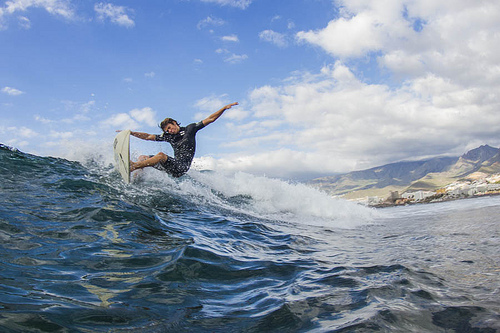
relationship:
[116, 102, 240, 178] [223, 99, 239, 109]
man has hand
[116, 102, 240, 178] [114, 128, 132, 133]
man has hand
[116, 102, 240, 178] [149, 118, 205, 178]
man wearing wet suit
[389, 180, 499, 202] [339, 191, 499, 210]
buildings on coast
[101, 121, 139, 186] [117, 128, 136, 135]
surfboard has tip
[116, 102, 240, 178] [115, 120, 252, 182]
man wearing navy blue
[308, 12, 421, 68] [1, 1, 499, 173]
clouds in sky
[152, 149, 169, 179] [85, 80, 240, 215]
knee of a man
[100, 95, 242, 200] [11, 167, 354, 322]
man surfing in ocean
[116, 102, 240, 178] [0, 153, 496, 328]
man riding on wave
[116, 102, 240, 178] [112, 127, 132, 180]
man riding on surfboard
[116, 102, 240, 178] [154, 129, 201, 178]
man in a wetsuit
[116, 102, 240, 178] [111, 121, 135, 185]
man falling off a surfboard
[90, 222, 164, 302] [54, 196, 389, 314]
reflection in water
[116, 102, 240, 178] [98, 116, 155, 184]
man holding onto a surfboard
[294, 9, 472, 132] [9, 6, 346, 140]
clouds in a sky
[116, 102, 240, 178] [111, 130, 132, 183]
man falling from surfboard